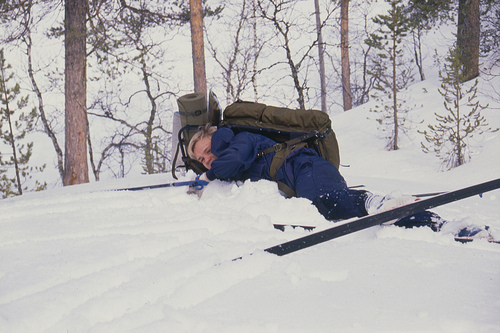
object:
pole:
[77, 176, 209, 193]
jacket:
[205, 124, 318, 195]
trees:
[402, 0, 435, 85]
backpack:
[171, 93, 337, 175]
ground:
[383, 152, 429, 183]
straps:
[268, 145, 289, 162]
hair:
[185, 123, 217, 158]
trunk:
[64, 10, 90, 182]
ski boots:
[364, 192, 418, 224]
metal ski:
[216, 177, 498, 274]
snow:
[2, 2, 498, 332]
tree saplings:
[421, 34, 488, 178]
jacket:
[205, 124, 318, 186]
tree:
[2, 44, 53, 198]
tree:
[251, 0, 310, 108]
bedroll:
[177, 92, 208, 174]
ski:
[257, 223, 497, 251]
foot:
[359, 189, 426, 213]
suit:
[209, 125, 490, 243]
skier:
[181, 122, 500, 248]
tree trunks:
[187, 1, 205, 97]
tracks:
[56, 246, 180, 329]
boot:
[444, 209, 491, 249]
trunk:
[61, 102, 94, 182]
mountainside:
[3, 1, 413, 326]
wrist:
[190, 169, 214, 190]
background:
[1, 2, 457, 131]